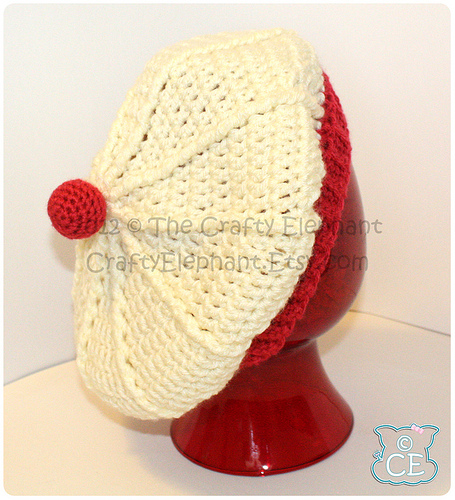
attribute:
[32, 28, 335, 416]
cap — white, handmade, display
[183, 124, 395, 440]
model — wide, red, white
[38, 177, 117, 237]
pom pom — small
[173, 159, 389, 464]
mannequin — red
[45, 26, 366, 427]
hat — crochet, yarn, red, handmade, white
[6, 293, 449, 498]
counter — white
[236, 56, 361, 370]
trim — red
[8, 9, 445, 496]
wall — gray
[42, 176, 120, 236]
ball — red